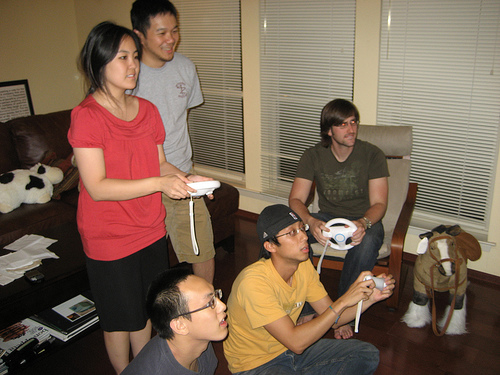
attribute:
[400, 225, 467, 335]
horse — stuffed, toy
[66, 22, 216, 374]
woman — gaming, smiling, playing, standing, asian, young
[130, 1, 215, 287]
man — smiling, standing, young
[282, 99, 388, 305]
man — sitting, gaming, playing, young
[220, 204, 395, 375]
guy — gaming, playing, young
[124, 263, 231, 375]
guy — young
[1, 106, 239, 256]
couch — brown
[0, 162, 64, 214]
cow — white, stuffed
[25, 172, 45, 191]
spot — black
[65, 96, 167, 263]
top — red, pink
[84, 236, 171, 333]
skirt — black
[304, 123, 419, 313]
chair — wood, brown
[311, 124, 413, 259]
cushion — beige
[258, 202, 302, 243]
cap — backwards, black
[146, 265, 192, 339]
hair — dark, black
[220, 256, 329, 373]
tshirt — yellow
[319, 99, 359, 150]
hair — light brown, brown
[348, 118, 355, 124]
eye — red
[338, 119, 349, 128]
eye — red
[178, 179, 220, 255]
controller — big, white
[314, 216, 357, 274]
steering wheel — big, white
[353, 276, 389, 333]
controller — big, white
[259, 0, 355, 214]
blinds — closed, white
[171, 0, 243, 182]
blinds — closed, white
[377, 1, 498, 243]
blinds — closed, white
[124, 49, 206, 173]
tshirt — gray